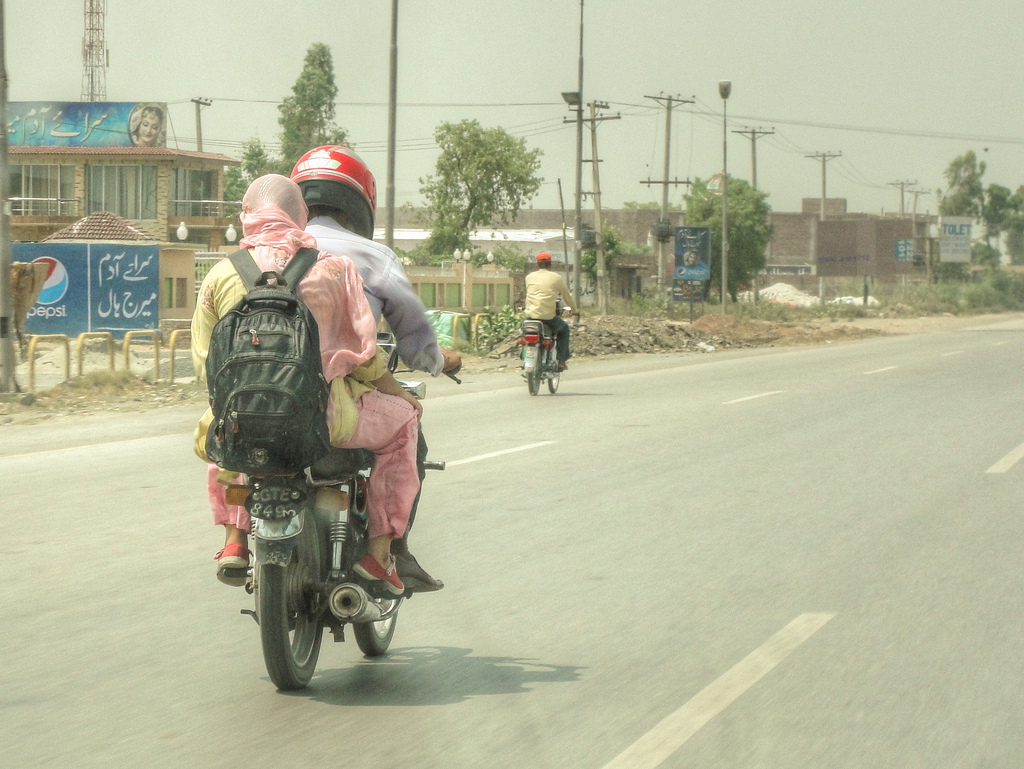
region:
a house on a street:
[13, 89, 222, 233]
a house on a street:
[380, 221, 570, 275]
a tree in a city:
[262, 32, 355, 168]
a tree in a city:
[416, 124, 528, 265]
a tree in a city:
[677, 175, 775, 308]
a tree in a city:
[931, 148, 983, 222]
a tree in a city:
[976, 172, 1008, 248]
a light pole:
[718, 66, 748, 316]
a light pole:
[560, 77, 600, 311]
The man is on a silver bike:
[517, 240, 574, 397]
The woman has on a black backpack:
[185, 170, 378, 592]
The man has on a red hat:
[520, 243, 581, 399]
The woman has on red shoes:
[211, 173, 405, 603]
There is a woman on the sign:
[8, 99, 171, 153]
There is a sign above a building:
[6, 97, 229, 237]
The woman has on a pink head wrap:
[182, 179, 389, 603]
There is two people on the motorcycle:
[179, 170, 446, 702]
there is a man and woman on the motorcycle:
[125, 166, 508, 698]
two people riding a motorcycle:
[171, 138, 465, 611]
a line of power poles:
[566, 81, 946, 236]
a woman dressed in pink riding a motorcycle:
[179, 170, 426, 611]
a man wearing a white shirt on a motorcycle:
[503, 245, 580, 405]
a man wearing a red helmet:
[276, 135, 467, 584]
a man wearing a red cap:
[512, 244, 579, 401]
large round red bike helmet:
[289, 147, 379, 234]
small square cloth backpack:
[208, 248, 330, 471]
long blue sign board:
[0, 103, 174, 151]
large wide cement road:
[1, 315, 1020, 765]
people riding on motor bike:
[192, 144, 450, 689]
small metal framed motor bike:
[513, 319, 578, 392]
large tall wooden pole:
[640, 87, 699, 280]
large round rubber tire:
[254, 540, 341, 697]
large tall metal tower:
[80, 3, 110, 106]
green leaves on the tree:
[957, 167, 1002, 219]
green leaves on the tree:
[708, 207, 738, 228]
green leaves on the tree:
[720, 207, 759, 255]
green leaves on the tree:
[439, 122, 458, 135]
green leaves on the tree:
[487, 144, 511, 160]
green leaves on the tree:
[455, 163, 466, 184]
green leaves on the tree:
[291, 46, 333, 82]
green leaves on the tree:
[296, 112, 328, 139]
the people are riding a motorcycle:
[111, 146, 448, 529]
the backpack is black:
[163, 303, 290, 412]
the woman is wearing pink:
[232, 202, 417, 561]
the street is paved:
[535, 417, 881, 724]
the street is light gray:
[548, 368, 932, 757]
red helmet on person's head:
[285, 142, 381, 240]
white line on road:
[609, 591, 840, 766]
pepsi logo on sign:
[19, 250, 68, 326]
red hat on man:
[537, 249, 558, 266]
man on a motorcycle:
[512, 250, 579, 396]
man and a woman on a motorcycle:
[183, 143, 468, 695]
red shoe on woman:
[353, 552, 410, 606]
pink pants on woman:
[318, 377, 421, 554]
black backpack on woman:
[212, 239, 321, 480]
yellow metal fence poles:
[21, 316, 196, 392]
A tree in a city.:
[410, 106, 524, 262]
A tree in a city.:
[265, 42, 363, 180]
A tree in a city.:
[198, 137, 287, 221]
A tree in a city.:
[575, 217, 642, 298]